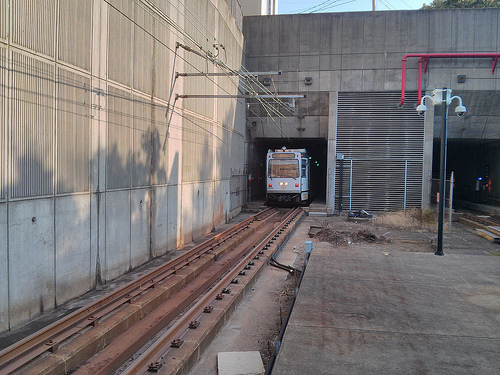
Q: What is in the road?
A: Wall.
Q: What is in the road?
A: Wires.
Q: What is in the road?
A: Shadows.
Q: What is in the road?
A: Lights.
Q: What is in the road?
A: Tracks.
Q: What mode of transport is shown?
A: Train.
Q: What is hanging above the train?
A: Power lines.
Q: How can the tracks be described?
A: Rusty.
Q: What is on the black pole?
A: Security cameras.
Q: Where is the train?
A: Tunnel.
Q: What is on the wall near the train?
A: Shadows.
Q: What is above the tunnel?
A: Sky.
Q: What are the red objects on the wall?
A: Pipes.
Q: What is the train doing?
A: Exiting the tunnel.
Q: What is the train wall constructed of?
A: Concrete.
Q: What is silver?
A: Train.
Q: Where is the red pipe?
A: To the right.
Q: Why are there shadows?
A: Sunlight.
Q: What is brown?
A: Tracks.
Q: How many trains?
A: One.